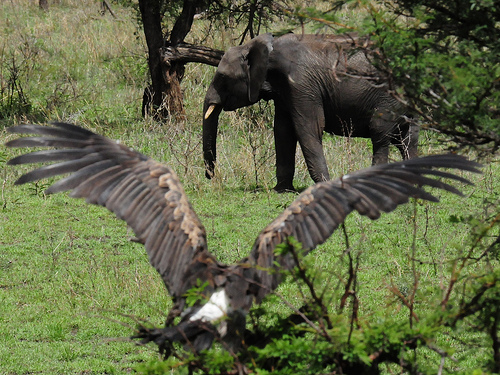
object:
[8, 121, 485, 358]
bird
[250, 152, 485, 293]
wing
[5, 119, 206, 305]
wing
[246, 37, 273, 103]
ear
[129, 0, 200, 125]
tree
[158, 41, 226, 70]
branch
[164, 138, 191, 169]
bush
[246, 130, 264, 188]
bush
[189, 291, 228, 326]
white feather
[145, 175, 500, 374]
tree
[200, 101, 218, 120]
tusks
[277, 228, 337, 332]
brush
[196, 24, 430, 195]
elephant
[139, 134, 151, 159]
weeds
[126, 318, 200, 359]
tail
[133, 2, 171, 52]
tree trunk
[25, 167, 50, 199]
grass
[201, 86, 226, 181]
trunk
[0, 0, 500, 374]
field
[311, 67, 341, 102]
skin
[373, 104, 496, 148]
bush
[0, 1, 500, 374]
ground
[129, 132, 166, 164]
food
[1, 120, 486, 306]
wingspan